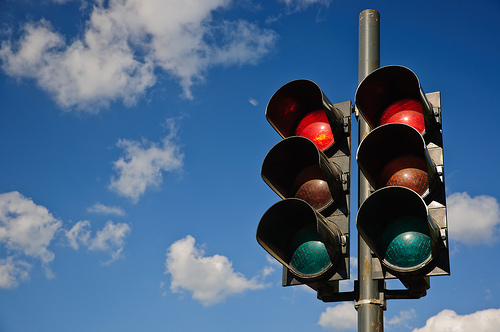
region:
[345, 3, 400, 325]
grey large pole of traffic light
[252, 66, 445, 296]
traffic lights in both sides of the pole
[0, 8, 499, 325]
cloudy light blue sky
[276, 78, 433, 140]
two red lights of the traffic lights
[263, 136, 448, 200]
two yellos lights of the traffic lights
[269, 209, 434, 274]
two green lights of the traffic lights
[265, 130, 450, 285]
four lights of traffic lights are turned off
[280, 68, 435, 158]
two lights that indicates stop are switched on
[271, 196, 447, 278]
two lights that means keeps driving are turned off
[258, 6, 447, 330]
traffic lights in fornt of a cloudy sky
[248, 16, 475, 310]
This is a light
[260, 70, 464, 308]
These lights are for two lanes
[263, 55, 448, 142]
This is a red light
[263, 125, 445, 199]
These lights are yellow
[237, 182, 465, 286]
These two are green lights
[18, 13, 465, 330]
There are clouds outside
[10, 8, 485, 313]
Blue is the color of the sky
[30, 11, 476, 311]
The time of day is day time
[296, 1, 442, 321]
The pole is black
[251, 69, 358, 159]
The inside is dirty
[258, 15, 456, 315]
A double stoplight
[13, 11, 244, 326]
A deep blue sky with wispy white clouds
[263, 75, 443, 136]
Two lit red lights on a stoplight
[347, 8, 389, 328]
A black metal pole holding a stop light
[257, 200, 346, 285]
Unlit green light on a traffic light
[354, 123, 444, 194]
Unlit yellow or caution light on a traffic light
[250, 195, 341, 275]
Circlular metal cover protecting the light from sun glare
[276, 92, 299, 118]
Reflection of a lit red light on black metal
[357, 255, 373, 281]
A spot of rust on a metal pole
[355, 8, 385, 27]
Rust spots on the top of a metal pole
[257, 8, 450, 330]
Stop light has three lights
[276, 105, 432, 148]
Lights are lit red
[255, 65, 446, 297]
Lights are red, green, yellow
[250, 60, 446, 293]
Stop lights have black cases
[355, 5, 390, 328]
metal pole holding street lights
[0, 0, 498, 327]
Sky is blue with clouds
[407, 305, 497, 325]
Thickest cloud is bottom right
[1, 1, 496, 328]
Scene is outdoor daytime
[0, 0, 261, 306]
Clouds are left of lights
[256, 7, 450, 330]
Light casing is casting shadow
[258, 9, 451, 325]
double electronic traffic signals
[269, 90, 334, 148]
red electric stop light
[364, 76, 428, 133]
red electric stop light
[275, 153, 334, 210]
yellow electric yield light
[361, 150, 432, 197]
yellow electric yield light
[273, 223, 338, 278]
green electric go light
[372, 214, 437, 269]
green electric go light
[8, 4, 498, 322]
a cloudy blue sky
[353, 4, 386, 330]
a tall metal pole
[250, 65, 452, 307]
double three way stop signals